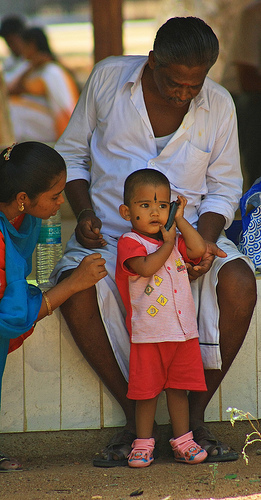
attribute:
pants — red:
[111, 327, 216, 407]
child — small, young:
[115, 168, 207, 467]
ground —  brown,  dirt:
[179, 86, 203, 119]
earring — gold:
[13, 196, 38, 222]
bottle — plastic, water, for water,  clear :
[36, 208, 61, 289]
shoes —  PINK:
[168, 429, 208, 465]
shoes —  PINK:
[127, 437, 155, 467]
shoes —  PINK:
[126, 430, 207, 467]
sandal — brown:
[91, 416, 161, 467]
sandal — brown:
[175, 426, 240, 462]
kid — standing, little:
[115, 167, 207, 467]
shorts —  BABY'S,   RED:
[125, 343, 205, 400]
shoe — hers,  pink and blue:
[127, 435, 157, 467]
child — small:
[113, 166, 215, 469]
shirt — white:
[53, 53, 243, 236]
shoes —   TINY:
[126, 438, 155, 469]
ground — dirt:
[1, 417, 256, 497]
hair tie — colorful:
[2, 138, 20, 164]